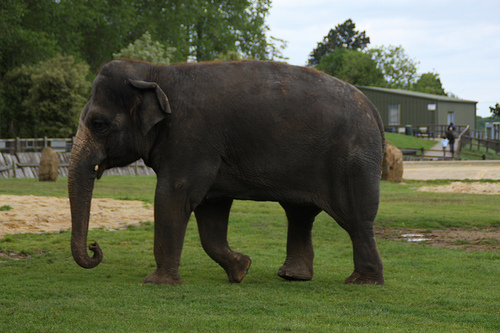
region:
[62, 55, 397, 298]
elephant walking on the grass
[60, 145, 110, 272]
bottom of the trunk is curled under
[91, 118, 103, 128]
eye on the side of the head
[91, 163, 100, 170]
small white tusk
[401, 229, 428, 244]
small puddles on the ground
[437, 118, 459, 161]
two people walking on the ramp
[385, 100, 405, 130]
window on the building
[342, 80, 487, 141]
dark green siding on the building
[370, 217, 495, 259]
a patch of mud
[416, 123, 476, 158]
black railing along the ramp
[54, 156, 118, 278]
trunk of the elephant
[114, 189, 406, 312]
legs of the elephant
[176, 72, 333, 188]
body of the elephant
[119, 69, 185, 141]
ear of the elephant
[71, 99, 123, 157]
eye of the elephant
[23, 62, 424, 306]
one elephant in the photo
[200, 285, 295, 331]
grass on the ground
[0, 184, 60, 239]
dirt on the ground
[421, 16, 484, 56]
sky above the land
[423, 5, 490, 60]
clouds in the sky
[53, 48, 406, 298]
An elephant in captivity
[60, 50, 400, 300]
An elephant in captivity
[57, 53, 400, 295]
An elephant in captivity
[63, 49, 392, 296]
An elephant in captivity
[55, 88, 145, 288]
The elephant has a trunk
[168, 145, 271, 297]
The elephant leg is bent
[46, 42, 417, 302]
The elephant is standing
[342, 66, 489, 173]
There is a building behind the elephant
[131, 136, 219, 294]
The elephant has a leg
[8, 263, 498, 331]
The grass is green and cut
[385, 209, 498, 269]
Mud puddle behind elephant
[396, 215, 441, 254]
Water puddle behind elephant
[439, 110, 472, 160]
Person standing on walkway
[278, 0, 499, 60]
The sky is clear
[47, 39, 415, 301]
the elephant on the grass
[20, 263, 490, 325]
the grass is trimmed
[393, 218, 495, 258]
patch of sand in the grass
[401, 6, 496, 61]
the sky is blue and clear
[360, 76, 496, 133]
the green building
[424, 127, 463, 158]
the ramp to the green building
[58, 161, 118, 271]
the trunk of the elephant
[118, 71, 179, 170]
ear of the elephant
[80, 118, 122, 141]
eye of the elephant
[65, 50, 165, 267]
the head of the elephant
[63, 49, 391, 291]
An elephant walking on the lawn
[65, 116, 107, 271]
the trunk of an adult elephant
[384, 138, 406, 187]
A bale of hay for the elephant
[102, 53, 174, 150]
An ear on the elephants head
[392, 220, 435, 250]
A small puddle in the mud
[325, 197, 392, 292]
The back leg of a full-grown elephant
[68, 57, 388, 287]
elephant is walking on grass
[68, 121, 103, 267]
trunk belongs to elephant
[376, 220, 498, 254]
dirt spot is in grass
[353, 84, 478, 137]
building is at the top of ramp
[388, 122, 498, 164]
ramp is in front o building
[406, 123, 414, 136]
trash can is at the top of ramp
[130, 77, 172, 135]
ear is apart of elephant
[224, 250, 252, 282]
elephant foot is lifted off grass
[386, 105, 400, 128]
window is apart of building